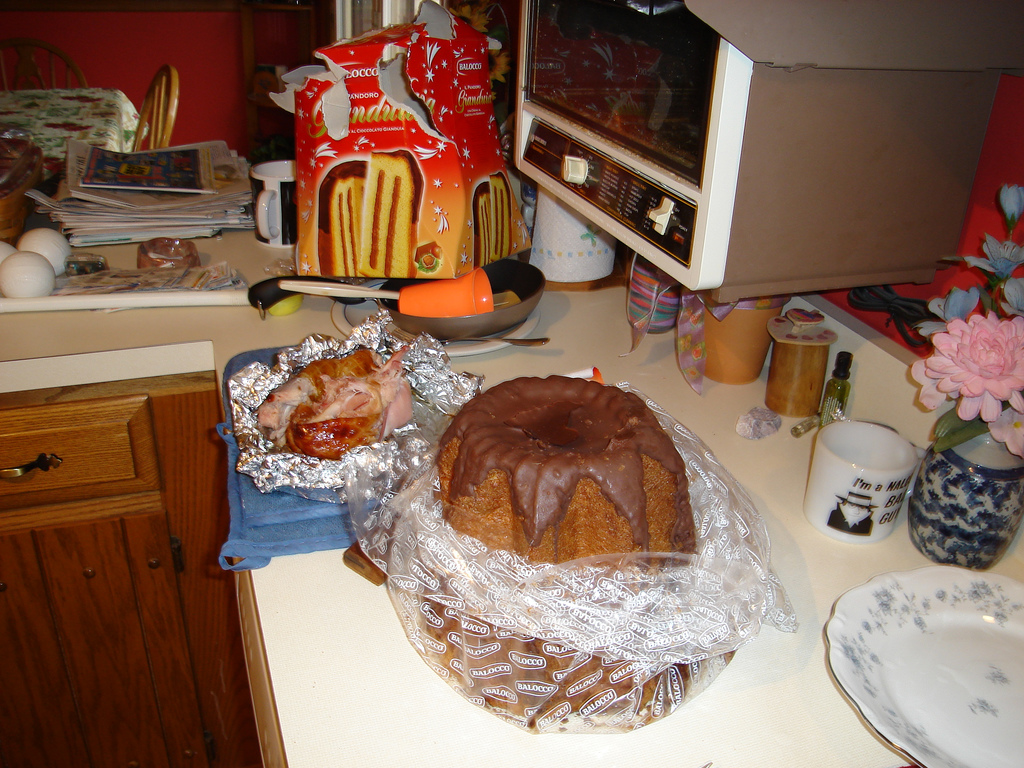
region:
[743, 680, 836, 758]
the counter top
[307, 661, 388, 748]
a white counter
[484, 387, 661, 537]
a brown cake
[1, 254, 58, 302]
a white egg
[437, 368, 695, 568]
food on the white counter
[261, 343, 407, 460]
food on the white counter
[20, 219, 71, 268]
food on the white counter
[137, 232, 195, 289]
food on the white counter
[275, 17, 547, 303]
food on the white counter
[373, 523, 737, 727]
food on the white counter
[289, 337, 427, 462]
food on the white counter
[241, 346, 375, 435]
food on the white counter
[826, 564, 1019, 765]
a white floral dinner plate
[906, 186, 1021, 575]
a vase of fake flowers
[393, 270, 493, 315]
an orange cup in a skillet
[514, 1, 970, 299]
a microwave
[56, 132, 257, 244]
a stack of newspaper on a counter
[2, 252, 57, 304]
a white ball on a counter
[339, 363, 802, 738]
bundt cake inside of plastic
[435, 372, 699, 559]
chocolate frosting on top of bunt cake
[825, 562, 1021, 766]
fancy white china plate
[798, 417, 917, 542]
white coffee mug with black writing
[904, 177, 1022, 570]
fake flowers in blue and white vase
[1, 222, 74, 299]
three white eggs on top of counter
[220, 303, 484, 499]
leftover turkey on foil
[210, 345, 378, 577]
blue oven mitts beneath foil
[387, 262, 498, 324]
plastic orange drinking cup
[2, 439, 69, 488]
the handle is bronze in color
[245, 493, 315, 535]
the towel is blue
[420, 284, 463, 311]
the cup is orange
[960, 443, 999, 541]
the vase is blue and white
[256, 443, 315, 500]
the aluminum is silver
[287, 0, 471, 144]
the box has been torn in different spots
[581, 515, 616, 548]
the cake is golden brown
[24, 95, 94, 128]
the table is cover with a tablecloth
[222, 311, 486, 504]
slices of meat on foil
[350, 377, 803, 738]
a cake wrapped in plastic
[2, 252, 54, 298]
a white chicken egg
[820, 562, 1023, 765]
a white and blue ceramic plate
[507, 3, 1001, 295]
a hanging kitchen tv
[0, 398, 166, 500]
a wooden kitchen drawer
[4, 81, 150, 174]
a white tablecloth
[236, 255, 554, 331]
a gray and black skillet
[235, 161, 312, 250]
a black and white coffee mug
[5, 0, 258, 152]
a painted red wall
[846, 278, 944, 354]
a bundled black cord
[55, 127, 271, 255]
a stack of papers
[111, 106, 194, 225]
a paper ont eh counter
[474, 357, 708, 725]
a cake on the counter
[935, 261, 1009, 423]
a flower in the vase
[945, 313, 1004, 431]
a pink flower in vase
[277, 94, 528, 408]
a box on the counter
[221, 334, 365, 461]
meat on the counter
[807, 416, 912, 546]
a black and white coffee mug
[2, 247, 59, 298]
a small white egg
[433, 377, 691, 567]
a small chocolate covered cake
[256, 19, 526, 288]
a red and yellow cake box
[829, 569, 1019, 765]
a blue and white plate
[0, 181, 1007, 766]
a white kitchen counter top